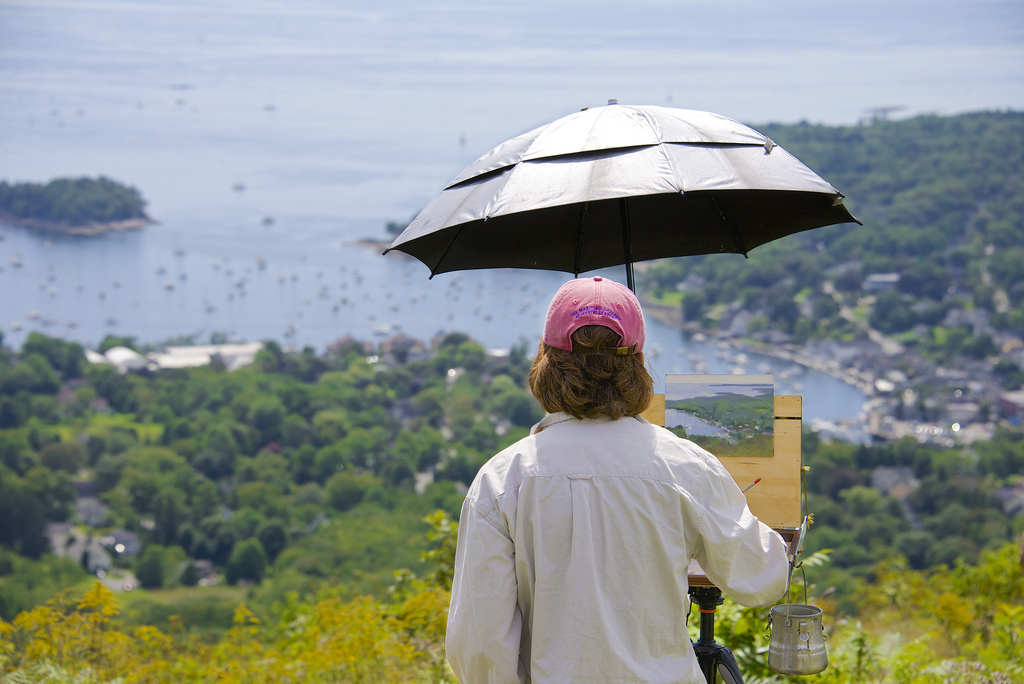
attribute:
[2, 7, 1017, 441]
water — blue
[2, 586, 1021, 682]
weeds — yellow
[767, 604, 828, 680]
bucket — shiny, silver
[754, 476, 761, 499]
tip — red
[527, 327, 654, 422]
hair — brown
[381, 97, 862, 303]
umbrella — open, black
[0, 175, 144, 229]
trees — green